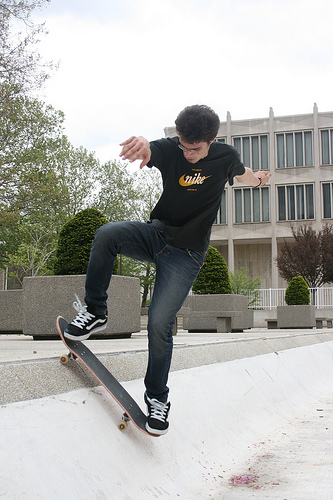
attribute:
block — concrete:
[36, 265, 154, 318]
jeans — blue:
[81, 217, 213, 405]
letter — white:
[185, 173, 197, 188]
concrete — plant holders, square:
[0, 285, 330, 498]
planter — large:
[287, 295, 315, 323]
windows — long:
[273, 180, 317, 220]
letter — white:
[169, 164, 215, 199]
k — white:
[192, 171, 201, 184]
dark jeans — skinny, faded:
[84, 216, 204, 400]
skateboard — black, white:
[47, 314, 175, 440]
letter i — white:
[192, 168, 197, 185]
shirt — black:
[155, 146, 226, 243]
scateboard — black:
[42, 309, 156, 440]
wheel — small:
[56, 349, 73, 368]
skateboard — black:
[55, 314, 160, 437]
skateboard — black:
[55, 288, 182, 453]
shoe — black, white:
[143, 390, 171, 435]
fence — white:
[247, 287, 332, 330]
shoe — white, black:
[63, 305, 108, 340]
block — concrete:
[278, 303, 315, 330]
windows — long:
[285, 132, 295, 168]